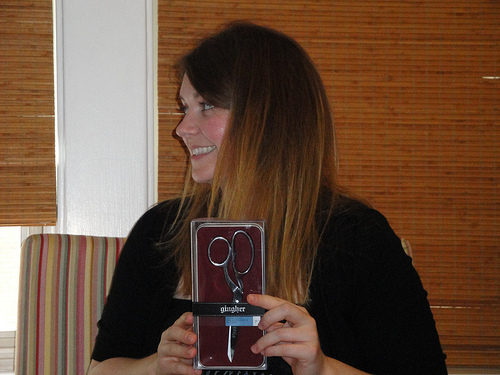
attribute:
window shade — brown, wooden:
[0, 0, 59, 228]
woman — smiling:
[92, 22, 452, 372]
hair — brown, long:
[226, 26, 329, 295]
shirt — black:
[80, 192, 452, 374]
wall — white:
[52, 1, 159, 233]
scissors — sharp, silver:
[205, 230, 254, 361]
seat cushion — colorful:
[18, 232, 127, 373]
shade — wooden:
[158, 1, 496, 362]